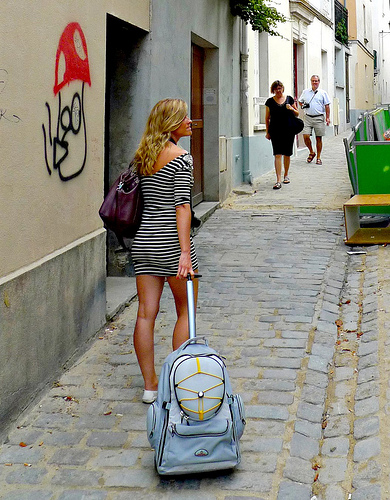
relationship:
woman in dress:
[98, 97, 200, 402] [132, 155, 199, 278]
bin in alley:
[345, 104, 388, 223] [1, 98, 386, 499]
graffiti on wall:
[43, 21, 88, 180] [3, 3, 149, 443]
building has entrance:
[149, 1, 232, 223] [191, 42, 205, 207]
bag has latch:
[146, 273, 245, 477] [197, 392, 205, 400]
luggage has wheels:
[146, 273, 245, 477] [149, 432, 244, 475]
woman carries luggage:
[98, 97, 200, 402] [146, 273, 245, 477]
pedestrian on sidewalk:
[299, 74, 331, 166] [224, 120, 353, 209]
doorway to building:
[293, 43, 303, 97] [241, 3, 336, 183]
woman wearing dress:
[98, 97, 200, 402] [132, 155, 199, 278]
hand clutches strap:
[285, 103, 293, 112] [287, 95, 295, 116]